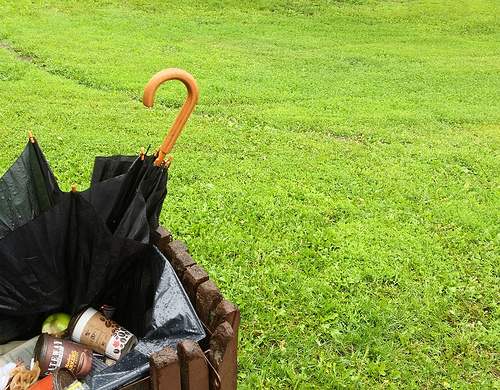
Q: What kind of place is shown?
A: It is a field.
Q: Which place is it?
A: It is a field.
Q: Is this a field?
A: Yes, it is a field.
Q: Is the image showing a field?
A: Yes, it is showing a field.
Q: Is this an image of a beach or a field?
A: It is showing a field.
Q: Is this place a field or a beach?
A: It is a field.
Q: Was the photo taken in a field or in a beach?
A: It was taken at a field.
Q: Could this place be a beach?
A: No, it is a field.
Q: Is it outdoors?
A: Yes, it is outdoors.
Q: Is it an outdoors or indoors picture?
A: It is outdoors.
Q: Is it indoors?
A: No, it is outdoors.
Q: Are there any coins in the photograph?
A: No, there are no coins.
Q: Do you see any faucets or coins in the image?
A: No, there are no coins or faucets.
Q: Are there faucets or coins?
A: No, there are no coins or faucets.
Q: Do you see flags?
A: No, there are no flags.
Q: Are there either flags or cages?
A: No, there are no flags or cages.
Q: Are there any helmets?
A: No, there are no helmets.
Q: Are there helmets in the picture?
A: No, there are no helmets.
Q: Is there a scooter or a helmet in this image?
A: No, there are no helmets or scooters.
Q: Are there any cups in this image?
A: Yes, there is a cup.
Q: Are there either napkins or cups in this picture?
A: Yes, there is a cup.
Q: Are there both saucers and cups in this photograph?
A: No, there is a cup but no saucers.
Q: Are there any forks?
A: No, there are no forks.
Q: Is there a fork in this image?
A: No, there are no forks.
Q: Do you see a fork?
A: No, there are no forks.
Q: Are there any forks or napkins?
A: No, there are no forks or napkins.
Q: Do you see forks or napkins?
A: No, there are no forks or napkins.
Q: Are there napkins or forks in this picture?
A: No, there are no forks or napkins.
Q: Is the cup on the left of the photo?
A: Yes, the cup is on the left of the image.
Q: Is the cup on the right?
A: No, the cup is on the left of the image.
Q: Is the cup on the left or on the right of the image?
A: The cup is on the left of the image.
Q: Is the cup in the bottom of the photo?
A: Yes, the cup is in the bottom of the image.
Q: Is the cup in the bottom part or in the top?
A: The cup is in the bottom of the image.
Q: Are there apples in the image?
A: Yes, there is an apple.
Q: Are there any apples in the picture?
A: Yes, there is an apple.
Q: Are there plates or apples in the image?
A: Yes, there is an apple.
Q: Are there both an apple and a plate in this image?
A: No, there is an apple but no plates.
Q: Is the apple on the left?
A: Yes, the apple is on the left of the image.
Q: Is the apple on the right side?
A: No, the apple is on the left of the image.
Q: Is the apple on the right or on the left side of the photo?
A: The apple is on the left of the image.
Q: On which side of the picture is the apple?
A: The apple is on the left of the image.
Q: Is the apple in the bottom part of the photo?
A: Yes, the apple is in the bottom of the image.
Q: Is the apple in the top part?
A: No, the apple is in the bottom of the image.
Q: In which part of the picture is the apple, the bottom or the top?
A: The apple is in the bottom of the image.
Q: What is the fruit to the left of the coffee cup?
A: The fruit is an apple.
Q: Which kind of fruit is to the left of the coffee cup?
A: The fruit is an apple.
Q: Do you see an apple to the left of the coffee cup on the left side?
A: Yes, there is an apple to the left of the coffee cup.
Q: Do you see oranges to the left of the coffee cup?
A: No, there is an apple to the left of the coffee cup.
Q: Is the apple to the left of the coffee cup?
A: Yes, the apple is to the left of the coffee cup.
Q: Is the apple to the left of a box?
A: No, the apple is to the left of the coffee cup.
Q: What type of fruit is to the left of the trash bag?
A: The fruit is an apple.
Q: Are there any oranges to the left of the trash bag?
A: No, there is an apple to the left of the trash bag.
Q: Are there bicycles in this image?
A: No, there are no bicycles.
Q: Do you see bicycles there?
A: No, there are no bicycles.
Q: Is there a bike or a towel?
A: No, there are no bikes or towels.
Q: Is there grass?
A: Yes, there is grass.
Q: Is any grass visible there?
A: Yes, there is grass.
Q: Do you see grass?
A: Yes, there is grass.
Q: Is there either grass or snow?
A: Yes, there is grass.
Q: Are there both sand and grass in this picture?
A: No, there is grass but no sand.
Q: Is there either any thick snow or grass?
A: Yes, there is thick grass.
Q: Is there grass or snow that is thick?
A: Yes, the grass is thick.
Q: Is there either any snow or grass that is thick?
A: Yes, the grass is thick.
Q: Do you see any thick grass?
A: Yes, there is thick grass.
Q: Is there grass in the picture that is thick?
A: Yes, there is grass that is thick.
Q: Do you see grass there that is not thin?
A: Yes, there is thick grass.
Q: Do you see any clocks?
A: No, there are no clocks.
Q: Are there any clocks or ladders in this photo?
A: No, there are no clocks or ladders.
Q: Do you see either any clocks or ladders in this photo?
A: No, there are no clocks or ladders.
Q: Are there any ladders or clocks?
A: No, there are no clocks or ladders.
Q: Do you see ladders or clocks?
A: No, there are no clocks or ladders.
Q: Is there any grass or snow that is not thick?
A: No, there is grass but it is thick.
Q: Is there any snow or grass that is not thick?
A: No, there is grass but it is thick.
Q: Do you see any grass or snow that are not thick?
A: No, there is grass but it is thick.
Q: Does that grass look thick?
A: Yes, the grass is thick.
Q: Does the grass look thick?
A: Yes, the grass is thick.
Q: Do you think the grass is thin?
A: No, the grass is thick.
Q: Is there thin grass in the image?
A: No, there is grass but it is thick.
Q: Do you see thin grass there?
A: No, there is grass but it is thick.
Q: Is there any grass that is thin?
A: No, there is grass but it is thick.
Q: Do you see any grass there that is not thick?
A: No, there is grass but it is thick.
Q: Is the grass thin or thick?
A: The grass is thick.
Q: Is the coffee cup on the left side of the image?
A: Yes, the coffee cup is on the left of the image.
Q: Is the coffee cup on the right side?
A: No, the coffee cup is on the left of the image.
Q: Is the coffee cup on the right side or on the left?
A: The coffee cup is on the left of the image.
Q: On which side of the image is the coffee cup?
A: The coffee cup is on the left of the image.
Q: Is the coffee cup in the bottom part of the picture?
A: Yes, the coffee cup is in the bottom of the image.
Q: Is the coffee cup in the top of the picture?
A: No, the coffee cup is in the bottom of the image.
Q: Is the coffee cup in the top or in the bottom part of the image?
A: The coffee cup is in the bottom of the image.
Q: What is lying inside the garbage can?
A: The coffee cup is lying inside the garbage can.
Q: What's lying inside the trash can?
A: The coffee cup is lying inside the garbage can.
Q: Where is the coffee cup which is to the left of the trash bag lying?
A: The coffee cup is lying inside the trash can.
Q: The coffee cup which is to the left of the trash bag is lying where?
A: The coffee cup is lying inside the trash can.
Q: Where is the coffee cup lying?
A: The coffee cup is lying inside the trash can.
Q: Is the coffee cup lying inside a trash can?
A: Yes, the coffee cup is lying inside a trash can.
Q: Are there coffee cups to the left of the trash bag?
A: Yes, there is a coffee cup to the left of the trash bag.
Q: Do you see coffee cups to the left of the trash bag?
A: Yes, there is a coffee cup to the left of the trash bag.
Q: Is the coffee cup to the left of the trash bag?
A: Yes, the coffee cup is to the left of the trash bag.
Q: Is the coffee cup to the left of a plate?
A: No, the coffee cup is to the left of the trash bag.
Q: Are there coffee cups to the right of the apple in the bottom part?
A: Yes, there is a coffee cup to the right of the apple.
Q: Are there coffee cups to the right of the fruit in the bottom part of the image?
A: Yes, there is a coffee cup to the right of the apple.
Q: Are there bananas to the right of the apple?
A: No, there is a coffee cup to the right of the apple.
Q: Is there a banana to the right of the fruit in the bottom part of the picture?
A: No, there is a coffee cup to the right of the apple.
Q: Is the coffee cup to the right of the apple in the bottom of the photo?
A: Yes, the coffee cup is to the right of the apple.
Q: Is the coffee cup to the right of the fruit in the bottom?
A: Yes, the coffee cup is to the right of the apple.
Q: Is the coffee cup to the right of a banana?
A: No, the coffee cup is to the right of the apple.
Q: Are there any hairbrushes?
A: No, there are no hairbrushes.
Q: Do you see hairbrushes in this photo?
A: No, there are no hairbrushes.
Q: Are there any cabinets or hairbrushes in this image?
A: No, there are no hairbrushes or cabinets.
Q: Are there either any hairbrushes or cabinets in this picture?
A: No, there are no hairbrushes or cabinets.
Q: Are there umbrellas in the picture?
A: Yes, there is an umbrella.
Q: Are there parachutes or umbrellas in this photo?
A: Yes, there is an umbrella.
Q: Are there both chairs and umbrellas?
A: No, there is an umbrella but no chairs.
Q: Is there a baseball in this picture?
A: No, there are no baseballs.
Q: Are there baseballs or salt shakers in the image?
A: No, there are no baseballs or salt shakers.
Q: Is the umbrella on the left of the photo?
A: Yes, the umbrella is on the left of the image.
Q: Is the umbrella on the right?
A: No, the umbrella is on the left of the image.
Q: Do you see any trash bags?
A: Yes, there is a trash bag.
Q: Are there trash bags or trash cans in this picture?
A: Yes, there is a trash bag.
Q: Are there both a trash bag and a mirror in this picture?
A: No, there is a trash bag but no mirrors.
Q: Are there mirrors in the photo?
A: No, there are no mirrors.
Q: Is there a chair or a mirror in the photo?
A: No, there are no mirrors or chairs.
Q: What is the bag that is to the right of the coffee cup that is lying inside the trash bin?
A: The bag is a trash bag.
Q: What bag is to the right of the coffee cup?
A: The bag is a trash bag.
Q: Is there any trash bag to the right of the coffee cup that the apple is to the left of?
A: Yes, there is a trash bag to the right of the coffee cup.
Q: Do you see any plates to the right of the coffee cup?
A: No, there is a trash bag to the right of the coffee cup.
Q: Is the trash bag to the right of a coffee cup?
A: Yes, the trash bag is to the right of a coffee cup.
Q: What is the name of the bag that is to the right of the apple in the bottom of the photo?
A: The bag is a trash bag.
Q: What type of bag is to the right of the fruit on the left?
A: The bag is a trash bag.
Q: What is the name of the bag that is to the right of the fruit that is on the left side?
A: The bag is a trash bag.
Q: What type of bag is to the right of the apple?
A: The bag is a trash bag.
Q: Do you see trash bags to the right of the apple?
A: Yes, there is a trash bag to the right of the apple.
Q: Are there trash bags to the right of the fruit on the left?
A: Yes, there is a trash bag to the right of the apple.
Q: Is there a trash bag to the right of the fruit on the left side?
A: Yes, there is a trash bag to the right of the apple.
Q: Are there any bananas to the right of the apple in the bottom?
A: No, there is a trash bag to the right of the apple.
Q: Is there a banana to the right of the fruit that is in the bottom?
A: No, there is a trash bag to the right of the apple.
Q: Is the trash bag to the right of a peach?
A: No, the trash bag is to the right of the apple.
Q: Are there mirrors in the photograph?
A: No, there are no mirrors.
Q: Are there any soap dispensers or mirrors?
A: No, there are no mirrors or soap dispensers.